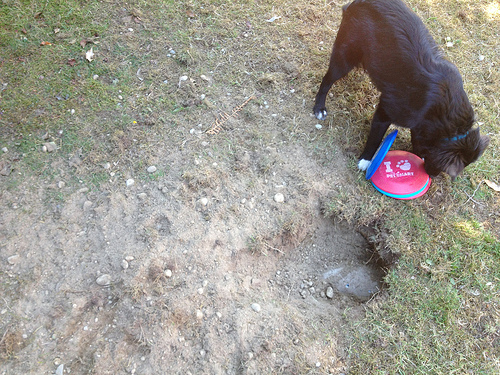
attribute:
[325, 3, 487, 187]
dog — black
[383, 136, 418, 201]
kits — red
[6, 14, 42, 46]
grass — green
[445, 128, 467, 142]
collar — blue